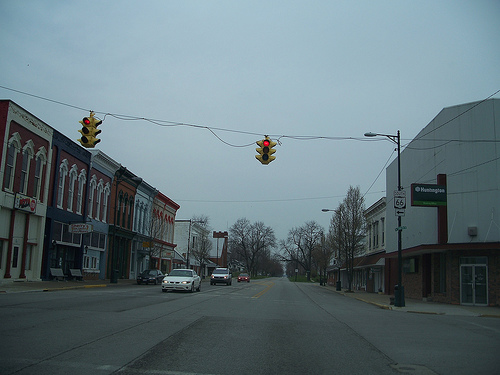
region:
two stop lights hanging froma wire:
[65, 96, 349, 170]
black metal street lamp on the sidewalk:
[363, 125, 415, 313]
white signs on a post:
[385, 183, 412, 244]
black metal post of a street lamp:
[382, 123, 414, 310]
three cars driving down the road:
[148, 254, 257, 300]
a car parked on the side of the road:
[132, 263, 167, 292]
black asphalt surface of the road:
[226, 317, 324, 369]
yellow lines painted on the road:
[253, 270, 275, 307]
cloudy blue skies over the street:
[221, 37, 336, 104]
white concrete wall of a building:
[448, 148, 493, 206]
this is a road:
[233, 291, 309, 371]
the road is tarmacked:
[225, 295, 305, 373]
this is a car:
[163, 263, 203, 295]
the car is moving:
[161, 265, 203, 293]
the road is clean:
[248, 283, 312, 370]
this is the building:
[13, 153, 103, 255]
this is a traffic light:
[255, 134, 277, 164]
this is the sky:
[230, 16, 382, 91]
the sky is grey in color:
[177, 9, 364, 92]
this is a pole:
[388, 238, 411, 287]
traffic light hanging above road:
[249, 133, 279, 166]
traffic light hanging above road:
[76, 109, 103, 151]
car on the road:
[157, 262, 205, 299]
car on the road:
[207, 264, 238, 287]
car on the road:
[233, 268, 255, 285]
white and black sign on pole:
[389, 184, 407, 221]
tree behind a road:
[225, 217, 278, 275]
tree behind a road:
[266, 218, 330, 280]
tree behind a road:
[323, 182, 375, 298]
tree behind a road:
[134, 194, 177, 290]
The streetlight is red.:
[251, 128, 281, 169]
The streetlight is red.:
[72, 100, 107, 150]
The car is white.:
[157, 261, 207, 299]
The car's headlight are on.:
[158, 260, 206, 300]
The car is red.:
[233, 265, 255, 287]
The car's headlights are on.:
[234, 262, 259, 289]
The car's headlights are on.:
[203, 259, 238, 294]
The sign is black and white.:
[393, 205, 407, 216]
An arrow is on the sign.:
[389, 205, 410, 219]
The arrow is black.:
[388, 205, 408, 217]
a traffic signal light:
[254, 130, 285, 172]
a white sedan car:
[153, 264, 205, 296]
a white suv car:
[210, 264, 235, 286]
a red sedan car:
[237, 272, 252, 283]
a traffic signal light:
[74, 107, 109, 147]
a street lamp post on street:
[362, 127, 419, 309]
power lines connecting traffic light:
[1, 82, 498, 155]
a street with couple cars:
[6, 216, 498, 368]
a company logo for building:
[405, 181, 456, 209]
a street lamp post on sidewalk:
[311, 202, 352, 290]